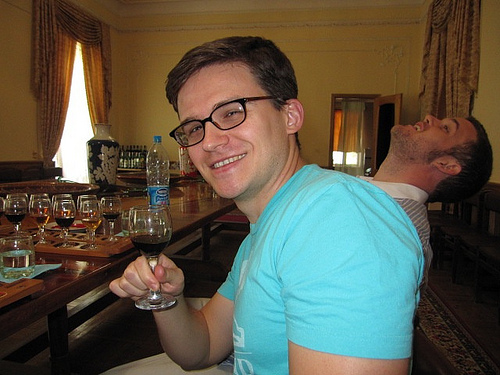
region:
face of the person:
[161, 53, 331, 239]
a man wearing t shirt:
[286, 243, 407, 374]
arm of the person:
[283, 282, 391, 372]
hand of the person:
[93, 237, 218, 358]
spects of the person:
[141, 76, 282, 144]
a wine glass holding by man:
[120, 171, 180, 326]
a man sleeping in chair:
[386, 95, 492, 200]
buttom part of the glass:
[131, 284, 194, 319]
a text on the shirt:
[226, 301, 263, 373]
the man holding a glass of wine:
[81, 21, 411, 372]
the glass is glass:
[115, 205, 197, 312]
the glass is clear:
[121, 201, 191, 311]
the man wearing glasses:
[135, 40, 290, 215]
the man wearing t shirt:
[135, 25, 425, 365]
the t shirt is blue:
[175, 165, 425, 370]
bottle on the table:
[135, 130, 185, 230]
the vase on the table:
[70, 110, 125, 195]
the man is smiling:
[175, 30, 315, 195]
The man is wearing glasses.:
[148, 112, 264, 155]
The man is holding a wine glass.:
[120, 184, 200, 310]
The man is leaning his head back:
[369, 104, 498, 195]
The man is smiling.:
[191, 133, 287, 177]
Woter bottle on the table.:
[126, 119, 183, 224]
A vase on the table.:
[77, 114, 122, 190]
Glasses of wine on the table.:
[15, 185, 115, 242]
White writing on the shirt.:
[213, 312, 265, 358]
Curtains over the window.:
[23, 13, 129, 134]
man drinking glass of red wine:
[108, 35, 430, 372]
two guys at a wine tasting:
[1, 35, 491, 372]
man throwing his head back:
[349, 110, 490, 220]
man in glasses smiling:
[163, 37, 309, 210]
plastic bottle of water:
[144, 135, 172, 219]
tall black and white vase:
[87, 120, 119, 197]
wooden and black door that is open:
[327, 94, 406, 183]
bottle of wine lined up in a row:
[116, 142, 151, 169]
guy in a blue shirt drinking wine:
[107, 34, 422, 373]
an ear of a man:
[282, 95, 305, 135]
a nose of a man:
[195, 120, 233, 155]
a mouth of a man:
[205, 148, 252, 174]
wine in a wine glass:
[123, 197, 184, 314]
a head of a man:
[381, 111, 493, 205]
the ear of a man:
[432, 152, 466, 178]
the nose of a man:
[421, 108, 439, 131]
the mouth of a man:
[406, 116, 426, 138]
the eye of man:
[439, 118, 455, 138]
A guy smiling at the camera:
[160, 31, 306, 196]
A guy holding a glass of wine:
[105, 28, 426, 365]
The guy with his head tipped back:
[375, 103, 499, 201]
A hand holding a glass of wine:
[107, 197, 187, 319]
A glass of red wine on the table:
[95, 191, 125, 245]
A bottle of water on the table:
[142, 129, 173, 216]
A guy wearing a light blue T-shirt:
[159, 30, 426, 372]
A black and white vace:
[84, 117, 124, 195]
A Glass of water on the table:
[2, 226, 37, 283]